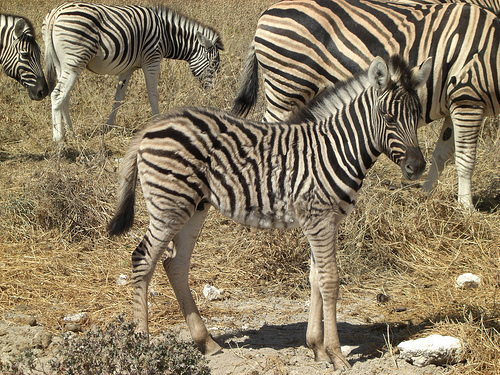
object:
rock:
[395, 332, 465, 367]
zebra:
[38, 1, 224, 143]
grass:
[77, 125, 113, 165]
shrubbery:
[0, 315, 197, 375]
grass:
[34, 242, 103, 305]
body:
[137, 110, 376, 208]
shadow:
[249, 322, 306, 350]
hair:
[389, 54, 414, 89]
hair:
[104, 192, 133, 237]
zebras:
[218, 0, 499, 209]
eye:
[22, 52, 30, 59]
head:
[190, 32, 219, 89]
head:
[368, 57, 433, 180]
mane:
[286, 68, 369, 123]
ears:
[411, 57, 434, 90]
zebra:
[104, 56, 432, 371]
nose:
[422, 159, 426, 165]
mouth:
[405, 172, 419, 181]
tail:
[107, 125, 143, 234]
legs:
[162, 204, 222, 355]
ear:
[369, 56, 389, 86]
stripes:
[140, 88, 382, 218]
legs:
[300, 210, 353, 372]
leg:
[129, 193, 192, 341]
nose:
[405, 165, 415, 174]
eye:
[383, 113, 397, 123]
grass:
[342, 189, 497, 286]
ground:
[0, 206, 497, 375]